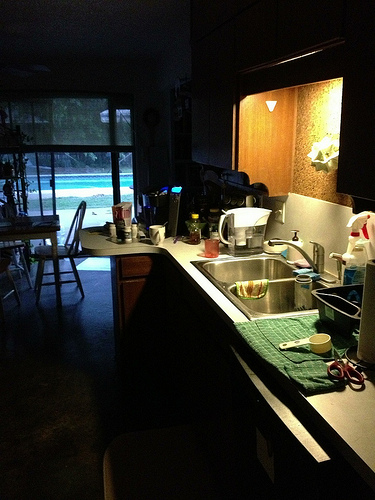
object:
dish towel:
[234, 315, 346, 395]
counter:
[81, 210, 375, 471]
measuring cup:
[279, 335, 330, 354]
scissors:
[327, 346, 362, 386]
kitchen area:
[0, 1, 375, 498]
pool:
[63, 175, 96, 199]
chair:
[34, 202, 87, 304]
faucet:
[267, 239, 325, 273]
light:
[313, 136, 339, 153]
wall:
[291, 76, 348, 271]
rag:
[236, 278, 269, 300]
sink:
[193, 259, 324, 318]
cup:
[148, 225, 166, 245]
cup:
[204, 240, 220, 258]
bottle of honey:
[190, 213, 201, 244]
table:
[0, 215, 66, 319]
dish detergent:
[343, 252, 363, 283]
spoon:
[160, 222, 167, 227]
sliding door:
[52, 95, 121, 234]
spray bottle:
[344, 211, 371, 270]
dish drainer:
[311, 283, 365, 331]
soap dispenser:
[285, 231, 304, 265]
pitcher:
[217, 201, 269, 255]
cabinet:
[190, 90, 297, 198]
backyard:
[12, 96, 137, 231]